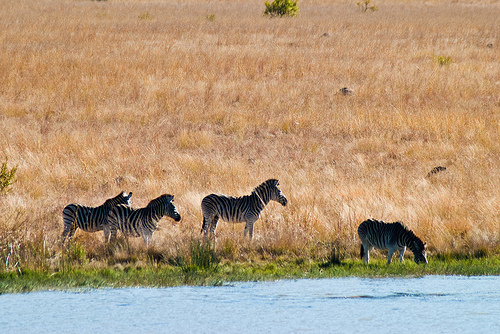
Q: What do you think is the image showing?
A: It is showing a field.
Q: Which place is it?
A: It is a field.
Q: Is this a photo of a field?
A: Yes, it is showing a field.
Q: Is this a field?
A: Yes, it is a field.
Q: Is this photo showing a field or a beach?
A: It is showing a field.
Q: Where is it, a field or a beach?
A: It is a field.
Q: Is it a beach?
A: No, it is a field.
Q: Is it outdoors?
A: Yes, it is outdoors.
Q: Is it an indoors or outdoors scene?
A: It is outdoors.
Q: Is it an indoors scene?
A: No, it is outdoors.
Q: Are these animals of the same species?
A: Yes, all the animals are zebras.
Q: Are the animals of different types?
A: No, all the animals are zebras.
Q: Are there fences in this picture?
A: No, there are no fences.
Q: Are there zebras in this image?
A: Yes, there are zebras.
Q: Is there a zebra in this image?
A: Yes, there are zebras.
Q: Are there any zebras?
A: Yes, there are zebras.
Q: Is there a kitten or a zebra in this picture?
A: Yes, there are zebras.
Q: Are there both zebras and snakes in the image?
A: No, there are zebras but no snakes.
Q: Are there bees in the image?
A: No, there are no bees.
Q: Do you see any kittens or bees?
A: No, there are no bees or kittens.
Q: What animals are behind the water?
A: The animals are zebras.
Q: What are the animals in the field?
A: The animals are zebras.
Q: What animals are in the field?
A: The animals are zebras.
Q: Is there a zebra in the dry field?
A: Yes, there are zebras in the field.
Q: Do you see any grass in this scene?
A: Yes, there is grass.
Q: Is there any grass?
A: Yes, there is grass.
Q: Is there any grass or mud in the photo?
A: Yes, there is grass.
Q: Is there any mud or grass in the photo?
A: Yes, there is grass.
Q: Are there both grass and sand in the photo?
A: No, there is grass but no sand.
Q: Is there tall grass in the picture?
A: Yes, there is tall grass.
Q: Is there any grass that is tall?
A: Yes, there is grass that is tall.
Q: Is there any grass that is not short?
A: Yes, there is tall grass.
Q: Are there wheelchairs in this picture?
A: No, there are no wheelchairs.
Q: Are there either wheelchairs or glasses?
A: No, there are no wheelchairs or glasses.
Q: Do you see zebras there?
A: Yes, there is a zebra.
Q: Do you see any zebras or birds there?
A: Yes, there is a zebra.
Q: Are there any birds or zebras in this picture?
A: Yes, there is a zebra.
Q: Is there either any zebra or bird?
A: Yes, there is a zebra.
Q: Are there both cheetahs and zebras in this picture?
A: No, there is a zebra but no cheetahs.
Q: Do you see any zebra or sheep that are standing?
A: Yes, the zebra is standing.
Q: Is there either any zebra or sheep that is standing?
A: Yes, the zebra is standing.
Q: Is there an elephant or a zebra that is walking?
A: Yes, the zebra is walking.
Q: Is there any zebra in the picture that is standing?
A: Yes, there is a zebra that is standing.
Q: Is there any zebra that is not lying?
A: Yes, there is a zebra that is standing.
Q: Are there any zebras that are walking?
A: Yes, there is a zebra that is walking.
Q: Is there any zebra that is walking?
A: Yes, there is a zebra that is walking.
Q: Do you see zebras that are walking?
A: Yes, there is a zebra that is walking.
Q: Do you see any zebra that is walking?
A: Yes, there is a zebra that is walking.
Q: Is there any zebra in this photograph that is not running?
A: Yes, there is a zebra that is walking.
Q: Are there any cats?
A: No, there are no cats.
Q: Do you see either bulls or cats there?
A: No, there are no cats or bulls.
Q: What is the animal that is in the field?
A: The animal is a zebra.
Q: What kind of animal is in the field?
A: The animal is a zebra.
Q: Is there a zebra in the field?
A: Yes, there is a zebra in the field.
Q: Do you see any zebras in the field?
A: Yes, there is a zebra in the field.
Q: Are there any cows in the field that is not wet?
A: No, there is a zebra in the field.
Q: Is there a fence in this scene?
A: No, there are no fences.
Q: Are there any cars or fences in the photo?
A: No, there are no fences or cars.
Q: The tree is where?
A: The tree is in the field.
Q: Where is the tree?
A: The tree is in the field.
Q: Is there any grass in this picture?
A: Yes, there is grass.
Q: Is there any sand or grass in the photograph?
A: Yes, there is grass.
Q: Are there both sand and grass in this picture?
A: No, there is grass but no sand.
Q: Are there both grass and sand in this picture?
A: No, there is grass but no sand.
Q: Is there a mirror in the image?
A: No, there are no mirrors.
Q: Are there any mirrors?
A: No, there are no mirrors.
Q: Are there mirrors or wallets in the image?
A: No, there are no mirrors or wallets.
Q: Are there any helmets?
A: No, there are no helmets.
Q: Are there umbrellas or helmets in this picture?
A: No, there are no helmets or umbrellas.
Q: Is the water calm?
A: Yes, the water is calm.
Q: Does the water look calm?
A: Yes, the water is calm.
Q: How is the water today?
A: The water is calm.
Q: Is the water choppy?
A: No, the water is calm.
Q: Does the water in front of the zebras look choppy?
A: No, the water is calm.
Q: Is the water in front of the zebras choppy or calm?
A: The water is calm.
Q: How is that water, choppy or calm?
A: The water is calm.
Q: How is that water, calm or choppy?
A: The water is calm.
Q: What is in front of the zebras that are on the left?
A: The water is in front of the zebras.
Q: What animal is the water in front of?
A: The water is in front of the zebras.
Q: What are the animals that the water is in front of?
A: The animals are zebras.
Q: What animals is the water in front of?
A: The water is in front of the zebras.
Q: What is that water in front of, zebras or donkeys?
A: The water is in front of zebras.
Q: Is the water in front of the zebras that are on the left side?
A: Yes, the water is in front of the zebras.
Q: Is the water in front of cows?
A: No, the water is in front of the zebras.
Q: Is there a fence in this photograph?
A: No, there are no fences.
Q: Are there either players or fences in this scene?
A: No, there are no fences or players.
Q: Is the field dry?
A: Yes, the field is dry.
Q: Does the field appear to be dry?
A: Yes, the field is dry.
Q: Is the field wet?
A: No, the field is dry.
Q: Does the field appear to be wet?
A: No, the field is dry.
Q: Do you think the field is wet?
A: No, the field is dry.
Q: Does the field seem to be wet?
A: No, the field is dry.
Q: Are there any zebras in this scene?
A: Yes, there is a zebra.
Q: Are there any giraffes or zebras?
A: Yes, there is a zebra.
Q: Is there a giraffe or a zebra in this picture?
A: Yes, there is a zebra.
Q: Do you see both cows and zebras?
A: No, there is a zebra but no cows.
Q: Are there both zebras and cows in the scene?
A: No, there is a zebra but no cows.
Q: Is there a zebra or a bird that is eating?
A: Yes, the zebra is eating.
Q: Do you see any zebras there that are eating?
A: Yes, there is a zebra that is eating.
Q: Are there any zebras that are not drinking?
A: Yes, there is a zebra that is eating.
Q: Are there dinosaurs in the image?
A: No, there are no dinosaurs.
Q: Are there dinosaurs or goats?
A: No, there are no dinosaurs or goats.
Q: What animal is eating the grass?
A: The zebra is eating the grass.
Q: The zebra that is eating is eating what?
A: The zebra is eating grass.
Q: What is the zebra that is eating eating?
A: The zebra is eating grass.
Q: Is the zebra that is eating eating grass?
A: Yes, the zebra is eating grass.